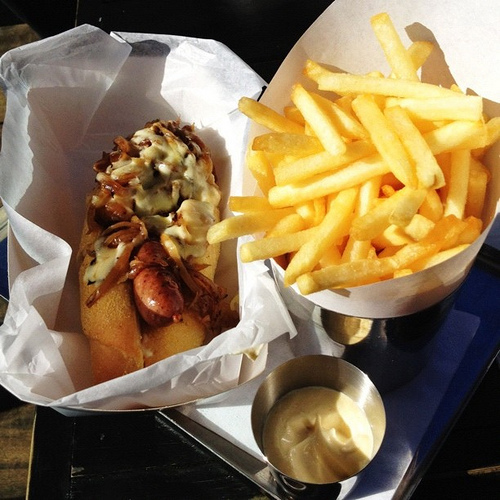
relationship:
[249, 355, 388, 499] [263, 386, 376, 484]
container has sauce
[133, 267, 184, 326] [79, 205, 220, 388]
hot dog in bun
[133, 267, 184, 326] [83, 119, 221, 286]
hot dog has cheese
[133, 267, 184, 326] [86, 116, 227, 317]
hot dog has onion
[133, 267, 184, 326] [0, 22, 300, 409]
hot dog on paper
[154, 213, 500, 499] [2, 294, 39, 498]
tray on table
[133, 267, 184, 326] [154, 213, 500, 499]
hot dog on tray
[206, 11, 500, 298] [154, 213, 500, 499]
fries on tray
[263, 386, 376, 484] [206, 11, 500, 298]
sauce for fries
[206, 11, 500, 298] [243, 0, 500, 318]
fries in container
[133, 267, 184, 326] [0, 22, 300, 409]
hot dog has paper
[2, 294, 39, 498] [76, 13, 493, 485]
table under food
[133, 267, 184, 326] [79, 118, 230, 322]
hot dog has toppings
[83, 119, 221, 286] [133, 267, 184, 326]
cheese on hot dog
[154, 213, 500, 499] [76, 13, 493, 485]
tray has food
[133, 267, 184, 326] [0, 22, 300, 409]
hot dog in paper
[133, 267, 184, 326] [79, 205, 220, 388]
hot dog on bun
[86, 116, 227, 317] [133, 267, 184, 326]
onion on hot dog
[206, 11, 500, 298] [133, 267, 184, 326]
fries next to hot dog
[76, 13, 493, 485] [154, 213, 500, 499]
food on tray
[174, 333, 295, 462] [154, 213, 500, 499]
napkin on tray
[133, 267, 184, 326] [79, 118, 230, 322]
hot dog under toppings